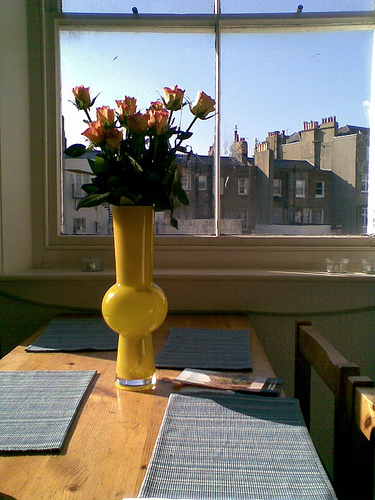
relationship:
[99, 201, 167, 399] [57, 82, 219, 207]
vase and flowers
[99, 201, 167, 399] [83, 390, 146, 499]
vase on table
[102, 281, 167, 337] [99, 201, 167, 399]
bulge on vase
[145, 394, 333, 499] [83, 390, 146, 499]
placemat on table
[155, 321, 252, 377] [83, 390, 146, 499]
placemat on table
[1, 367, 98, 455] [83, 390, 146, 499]
placemat on table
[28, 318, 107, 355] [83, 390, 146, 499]
placemat on table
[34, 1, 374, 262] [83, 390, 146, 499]
window behind table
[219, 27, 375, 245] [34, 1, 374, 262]
panel on window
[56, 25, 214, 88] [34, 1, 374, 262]
panel on window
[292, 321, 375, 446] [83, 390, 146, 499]
chairs at table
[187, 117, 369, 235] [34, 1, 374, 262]
buildings outside window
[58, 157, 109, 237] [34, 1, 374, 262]
buildings outside window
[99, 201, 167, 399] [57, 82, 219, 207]
vase with flowers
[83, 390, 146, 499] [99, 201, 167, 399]
table with vase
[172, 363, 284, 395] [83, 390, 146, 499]
pamphlet on table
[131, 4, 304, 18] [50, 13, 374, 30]
lock above frame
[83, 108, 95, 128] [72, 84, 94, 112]
stem of flower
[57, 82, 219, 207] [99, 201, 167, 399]
roses in vase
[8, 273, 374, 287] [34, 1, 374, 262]
sill of window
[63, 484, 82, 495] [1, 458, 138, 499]
knot in wood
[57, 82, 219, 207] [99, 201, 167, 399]
flowers in vase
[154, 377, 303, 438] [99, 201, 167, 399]
shadow of vase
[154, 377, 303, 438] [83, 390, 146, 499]
shadow on table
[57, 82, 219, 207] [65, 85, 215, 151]
bouquet of roses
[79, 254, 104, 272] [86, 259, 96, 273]
glass with candle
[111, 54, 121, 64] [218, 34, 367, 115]
bird in sky